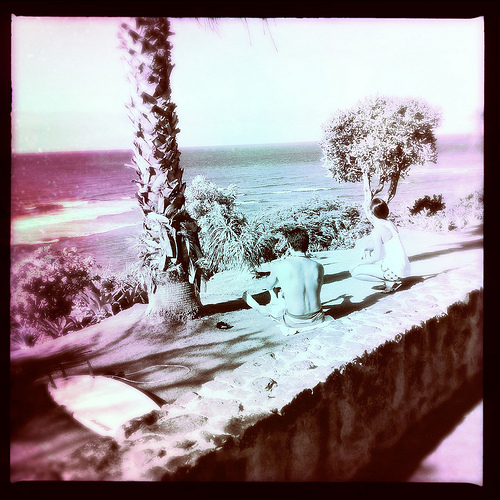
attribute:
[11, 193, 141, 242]
waves — small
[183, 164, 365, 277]
bushes — short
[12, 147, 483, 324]
ocean — smooth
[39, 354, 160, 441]
surfboard — white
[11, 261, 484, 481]
wall — low, concrete, stone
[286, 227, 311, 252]
hair — dark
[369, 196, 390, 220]
hair — brown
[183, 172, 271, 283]
tree — is palm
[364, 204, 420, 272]
top — tank 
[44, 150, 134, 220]
water — large body 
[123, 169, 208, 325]
tree — palm , trunk 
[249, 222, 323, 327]
man — dark hair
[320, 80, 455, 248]
tree — small 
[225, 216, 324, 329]
man — sitting down.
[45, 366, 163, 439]
surfboard — white  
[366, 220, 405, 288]
suit — bathing 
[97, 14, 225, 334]
tree — palm 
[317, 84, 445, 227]
tree — small 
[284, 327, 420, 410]
wall — brick 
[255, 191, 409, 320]
people — sitting down.